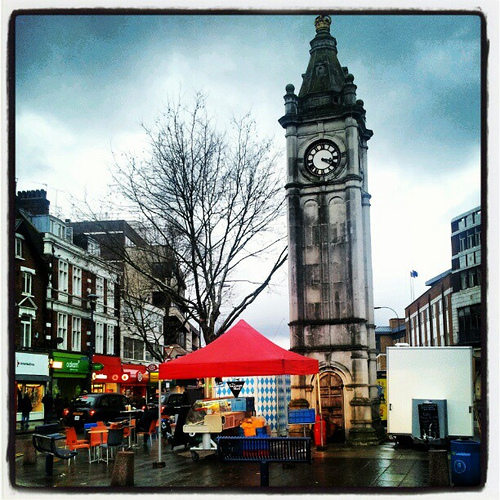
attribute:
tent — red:
[155, 322, 327, 460]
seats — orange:
[67, 422, 137, 467]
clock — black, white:
[303, 137, 347, 177]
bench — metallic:
[214, 436, 311, 485]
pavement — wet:
[17, 388, 484, 500]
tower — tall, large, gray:
[270, 13, 382, 444]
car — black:
[68, 387, 145, 434]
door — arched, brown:
[316, 370, 347, 444]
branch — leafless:
[227, 248, 293, 334]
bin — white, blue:
[450, 442, 476, 477]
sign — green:
[54, 354, 87, 381]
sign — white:
[15, 349, 48, 376]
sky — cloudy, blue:
[18, 16, 478, 330]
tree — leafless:
[95, 83, 292, 358]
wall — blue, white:
[212, 374, 287, 440]